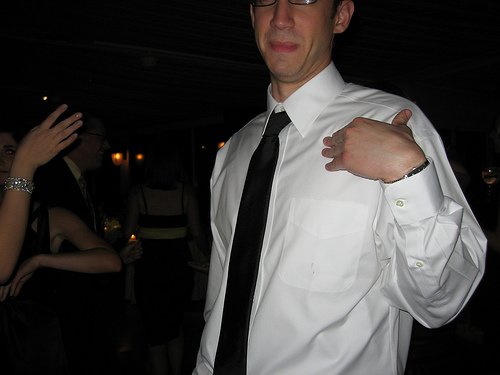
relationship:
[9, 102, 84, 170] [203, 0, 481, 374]
hand on man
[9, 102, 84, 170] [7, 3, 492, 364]
hand in air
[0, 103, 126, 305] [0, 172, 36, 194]
person wear bracelet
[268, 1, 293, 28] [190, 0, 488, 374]
nose of man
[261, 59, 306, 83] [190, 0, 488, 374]
jaw of man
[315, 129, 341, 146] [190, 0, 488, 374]
finger of man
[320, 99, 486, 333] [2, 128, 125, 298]
arm of person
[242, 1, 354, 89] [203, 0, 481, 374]
face of a grimacing man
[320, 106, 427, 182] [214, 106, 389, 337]
hand on h chest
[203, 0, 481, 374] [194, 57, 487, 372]
man hand touching h shirt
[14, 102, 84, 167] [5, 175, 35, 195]
hand and arm of woman wearing bracelet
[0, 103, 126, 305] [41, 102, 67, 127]
person has finger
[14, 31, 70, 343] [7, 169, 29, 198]
person has wrist